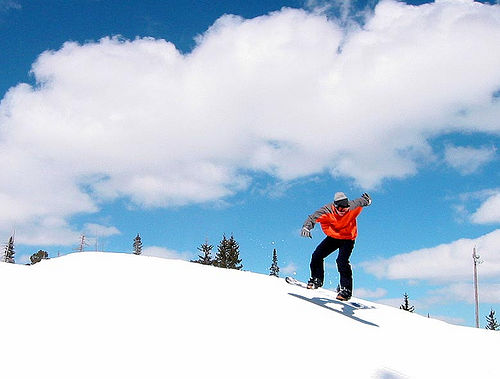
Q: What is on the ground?
A: Snow.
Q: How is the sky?
A: Blue with clouds.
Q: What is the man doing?
A: Snowboarding.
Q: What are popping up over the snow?
A: Trees.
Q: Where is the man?
A: On a snowy mountain.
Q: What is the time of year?
A: Winter.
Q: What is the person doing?
A: Snowboarding.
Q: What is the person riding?
A: Snowboard.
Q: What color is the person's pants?
A: Black.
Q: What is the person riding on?
A: Slope.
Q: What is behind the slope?
A: Trees.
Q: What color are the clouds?
A: White.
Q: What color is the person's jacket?
A: Orange and grey.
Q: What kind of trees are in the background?
A: Pine.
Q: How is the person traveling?
A: Snowboarding.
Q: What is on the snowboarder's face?
A: Goggles.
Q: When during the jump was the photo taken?
A: Before landing.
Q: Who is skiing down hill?
A: A man.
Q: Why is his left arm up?
A: Balance.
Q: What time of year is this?
A: Winter.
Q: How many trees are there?
A: Eight.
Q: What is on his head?
A: A helmet.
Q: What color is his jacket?
A: Red and gray.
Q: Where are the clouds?
A: Above.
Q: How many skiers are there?
A: One.